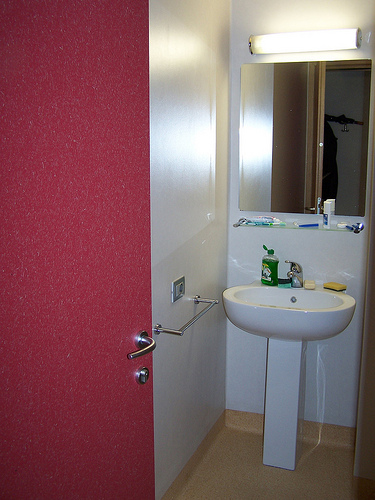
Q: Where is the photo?
A: Bathroom.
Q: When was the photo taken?
A: Morning.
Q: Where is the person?
A: Taking the photo.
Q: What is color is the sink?
A: White.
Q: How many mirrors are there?
A: One.